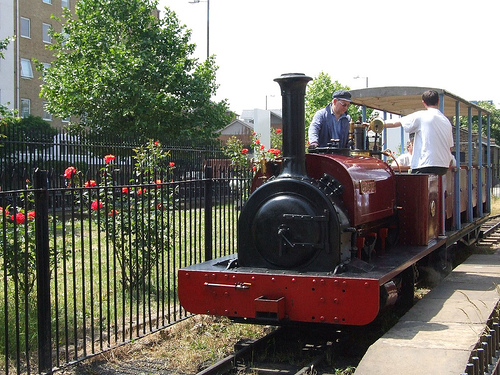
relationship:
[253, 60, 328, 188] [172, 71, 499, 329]
smoke stack on train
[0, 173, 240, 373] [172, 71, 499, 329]
fence next to train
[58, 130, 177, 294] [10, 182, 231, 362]
bush next to fence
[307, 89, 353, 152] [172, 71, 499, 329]
engineer at front of train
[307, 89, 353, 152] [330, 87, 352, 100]
engineer wears cap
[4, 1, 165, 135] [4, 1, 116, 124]
building has window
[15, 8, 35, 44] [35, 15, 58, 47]
window next window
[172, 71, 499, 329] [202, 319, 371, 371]
train on rails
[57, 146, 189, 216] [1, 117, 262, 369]
flowers behind behind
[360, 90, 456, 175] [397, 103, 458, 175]
man wears shirt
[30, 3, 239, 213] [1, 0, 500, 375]
tree in amusement park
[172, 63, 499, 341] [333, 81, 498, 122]
train has roof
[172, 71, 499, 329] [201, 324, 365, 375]
train has track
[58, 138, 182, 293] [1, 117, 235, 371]
bush behind fence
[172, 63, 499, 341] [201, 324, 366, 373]
train on track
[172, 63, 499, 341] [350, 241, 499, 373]
train has platform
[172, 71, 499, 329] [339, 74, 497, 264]
train pulls car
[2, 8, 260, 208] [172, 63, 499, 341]
buildings behind train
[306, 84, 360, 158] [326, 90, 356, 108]
engineer wears cap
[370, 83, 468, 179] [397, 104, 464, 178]
man wears shirt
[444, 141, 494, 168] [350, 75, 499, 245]
people in car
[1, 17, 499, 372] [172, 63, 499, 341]
amusement park has train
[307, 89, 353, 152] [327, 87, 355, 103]
engineer has hat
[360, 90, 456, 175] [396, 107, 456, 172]
man wearing shirt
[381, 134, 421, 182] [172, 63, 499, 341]
passenger on train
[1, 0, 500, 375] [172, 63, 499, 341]
amusement park has train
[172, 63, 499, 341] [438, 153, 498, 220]
train has seating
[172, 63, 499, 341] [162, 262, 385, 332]
train has grill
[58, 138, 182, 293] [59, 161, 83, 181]
bush has rose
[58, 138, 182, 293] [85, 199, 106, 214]
bush has rose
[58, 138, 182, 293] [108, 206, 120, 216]
bush has rose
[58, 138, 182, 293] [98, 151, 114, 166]
bush has rose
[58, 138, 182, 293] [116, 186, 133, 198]
bush has rose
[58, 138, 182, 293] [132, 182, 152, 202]
bush has rose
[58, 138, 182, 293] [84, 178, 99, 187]
bush has rose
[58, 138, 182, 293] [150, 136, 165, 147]
bush has rose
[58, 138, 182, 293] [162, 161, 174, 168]
bush has rose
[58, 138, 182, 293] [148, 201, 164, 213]
bush has rose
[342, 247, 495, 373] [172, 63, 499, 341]
ramp next to train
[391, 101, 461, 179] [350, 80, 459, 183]
shirt on man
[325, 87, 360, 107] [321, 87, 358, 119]
cap on head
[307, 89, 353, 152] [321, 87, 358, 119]
engineer has head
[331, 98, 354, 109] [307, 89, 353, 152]
sunglasses on engineer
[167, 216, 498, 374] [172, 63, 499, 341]
tracks under train